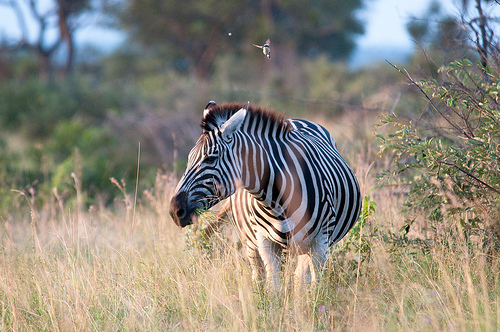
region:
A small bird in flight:
[242, 31, 283, 60]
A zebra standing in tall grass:
[145, 88, 365, 316]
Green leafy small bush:
[397, 65, 498, 244]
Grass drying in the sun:
[19, 215, 136, 318]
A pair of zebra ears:
[185, 100, 262, 142]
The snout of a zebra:
[165, 190, 201, 232]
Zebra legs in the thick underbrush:
[239, 237, 340, 318]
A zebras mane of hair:
[196, 92, 302, 141]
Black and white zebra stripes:
[280, 146, 328, 207]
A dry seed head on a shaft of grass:
[105, 172, 126, 191]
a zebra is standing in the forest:
[188, 90, 352, 286]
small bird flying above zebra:
[246, 33, 291, 60]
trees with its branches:
[11, 22, 146, 147]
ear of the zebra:
[218, 106, 245, 133]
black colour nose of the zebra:
[171, 200, 189, 221]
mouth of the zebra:
[169, 198, 199, 230]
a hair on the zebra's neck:
[226, 100, 301, 142]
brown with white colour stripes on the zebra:
[251, 150, 343, 200]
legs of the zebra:
[256, 237, 333, 330]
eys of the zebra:
[197, 148, 221, 171]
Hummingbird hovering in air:
[237, 23, 302, 76]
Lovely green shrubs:
[2, 85, 116, 191]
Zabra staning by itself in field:
[147, 83, 383, 310]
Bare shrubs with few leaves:
[355, 48, 498, 329]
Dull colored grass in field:
[0, 210, 128, 330]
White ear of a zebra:
[222, 108, 262, 137]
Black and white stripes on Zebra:
[280, 138, 347, 223]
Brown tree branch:
[186, 200, 239, 247]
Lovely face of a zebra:
[168, 122, 238, 232]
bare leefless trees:
[1, 4, 98, 83]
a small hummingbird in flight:
[252, 35, 277, 61]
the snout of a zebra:
[164, 186, 203, 231]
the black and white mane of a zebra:
[199, 94, 294, 142]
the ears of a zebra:
[199, 98, 250, 143]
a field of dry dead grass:
[0, 129, 499, 329]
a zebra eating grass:
[167, 89, 366, 288]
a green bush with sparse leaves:
[377, 55, 498, 272]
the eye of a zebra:
[197, 149, 221, 166]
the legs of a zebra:
[233, 230, 333, 305]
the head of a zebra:
[166, 95, 252, 229]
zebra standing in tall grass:
[153, 91, 370, 290]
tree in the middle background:
[118, 3, 368, 75]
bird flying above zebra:
[250, 31, 277, 65]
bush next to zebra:
[383, 11, 499, 222]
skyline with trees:
[5, 2, 492, 49]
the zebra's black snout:
[164, 196, 191, 233]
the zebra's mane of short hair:
[198, 96, 293, 138]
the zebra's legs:
[238, 231, 343, 284]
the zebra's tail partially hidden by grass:
[190, 208, 240, 241]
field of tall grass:
[11, 164, 498, 330]